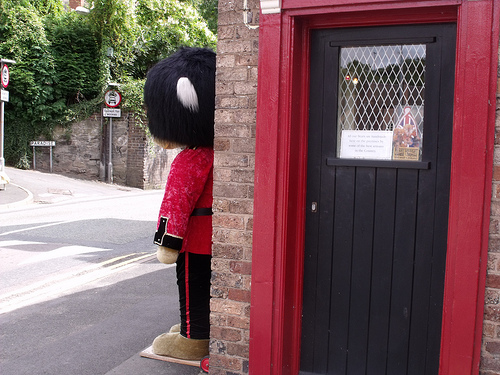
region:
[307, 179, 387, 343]
The door is black.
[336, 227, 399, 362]
The door is black.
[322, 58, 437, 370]
The door is black.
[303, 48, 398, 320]
The door is black.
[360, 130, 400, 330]
The door is black.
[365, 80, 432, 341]
The door is black.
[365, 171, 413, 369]
The door is black.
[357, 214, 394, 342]
The door is black.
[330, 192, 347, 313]
The door is black.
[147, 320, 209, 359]
Large brown feet of a creature with clothes on.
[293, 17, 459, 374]
A black door on a red frame.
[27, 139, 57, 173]
A sign held up by two poles against a wall.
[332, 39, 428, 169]
A window on a black door.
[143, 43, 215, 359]
A creature wearing black pants with a red stripe and big black furry helmet.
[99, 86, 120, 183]
A tall circle top sign against a wall.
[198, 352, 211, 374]
A red wheel.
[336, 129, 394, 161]
A white notice in a door window.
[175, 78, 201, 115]
White fur on a black furry helmet.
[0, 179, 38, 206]
A small curb.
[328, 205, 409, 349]
The door is black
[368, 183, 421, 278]
The door is black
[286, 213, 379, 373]
The door is black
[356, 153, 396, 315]
The door is black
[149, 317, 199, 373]
brown furry slippers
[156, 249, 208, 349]
black pant with red stripe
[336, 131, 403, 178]
white paper with black writing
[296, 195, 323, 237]
small white and gold door bell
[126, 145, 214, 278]
black and red jacket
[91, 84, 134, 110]
sign for a bus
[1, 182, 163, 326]
shadow on a cement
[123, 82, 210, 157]
black and white fluffy hat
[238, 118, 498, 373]
a red and black door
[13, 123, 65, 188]
small sign by stone wall